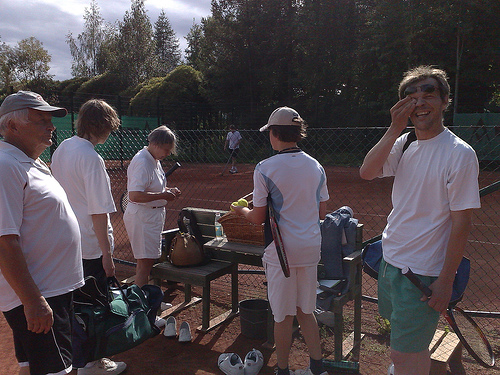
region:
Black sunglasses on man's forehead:
[395, 79, 448, 99]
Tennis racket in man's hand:
[392, 257, 497, 369]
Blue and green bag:
[55, 279, 176, 368]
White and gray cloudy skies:
[2, 2, 219, 88]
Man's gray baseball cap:
[0, 87, 71, 119]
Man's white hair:
[0, 105, 32, 143]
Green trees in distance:
[102, 2, 495, 85]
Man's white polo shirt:
[1, 139, 88, 322]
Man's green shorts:
[369, 252, 462, 360]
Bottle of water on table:
[207, 207, 228, 246]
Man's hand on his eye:
[372, 86, 425, 137]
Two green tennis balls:
[224, 192, 252, 217]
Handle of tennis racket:
[161, 158, 187, 182]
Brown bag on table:
[166, 223, 214, 270]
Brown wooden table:
[147, 247, 247, 341]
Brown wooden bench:
[156, 199, 373, 371]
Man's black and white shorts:
[3, 281, 101, 373]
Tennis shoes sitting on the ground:
[154, 309, 281, 373]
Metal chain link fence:
[21, 127, 496, 307]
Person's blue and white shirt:
[236, 150, 346, 253]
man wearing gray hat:
[8, 92, 101, 278]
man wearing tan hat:
[255, 110, 320, 280]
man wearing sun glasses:
[386, 73, 471, 198]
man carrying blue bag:
[379, 95, 477, 357]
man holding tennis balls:
[223, 82, 340, 237]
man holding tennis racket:
[378, 84, 497, 355]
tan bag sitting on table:
[150, 208, 237, 325]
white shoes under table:
[159, 285, 186, 335]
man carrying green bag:
[67, 110, 145, 364]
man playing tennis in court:
[213, 125, 272, 187]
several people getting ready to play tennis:
[1, 70, 496, 372]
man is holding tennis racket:
[356, 64, 496, 374]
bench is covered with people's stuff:
[153, 203, 364, 356]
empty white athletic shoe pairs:
[162, 315, 267, 370]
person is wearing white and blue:
[248, 148, 329, 324]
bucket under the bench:
[232, 296, 277, 344]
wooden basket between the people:
[217, 189, 281, 245]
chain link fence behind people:
[2, 120, 499, 369]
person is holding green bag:
[68, 277, 168, 362]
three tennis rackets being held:
[118, 160, 493, 372]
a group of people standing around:
[0, 68, 492, 374]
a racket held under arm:
[255, 177, 305, 284]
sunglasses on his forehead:
[389, 74, 447, 108]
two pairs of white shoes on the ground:
[156, 297, 274, 374]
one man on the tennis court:
[213, 116, 265, 190]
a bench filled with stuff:
[142, 195, 377, 371]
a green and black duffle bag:
[76, 263, 194, 370]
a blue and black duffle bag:
[347, 224, 489, 306]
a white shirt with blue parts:
[236, 128, 346, 299]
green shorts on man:
[361, 255, 458, 368]